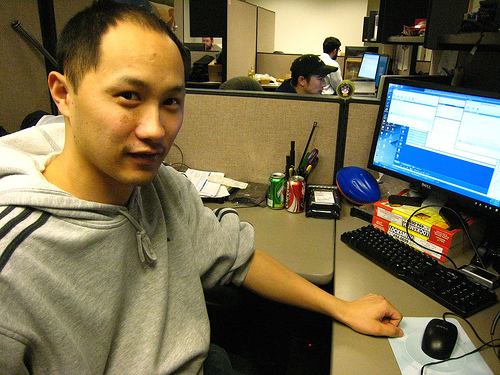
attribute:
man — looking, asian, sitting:
[0, 1, 405, 371]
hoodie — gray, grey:
[2, 120, 260, 373]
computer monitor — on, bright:
[364, 70, 499, 219]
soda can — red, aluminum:
[283, 169, 309, 216]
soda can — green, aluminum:
[264, 168, 288, 215]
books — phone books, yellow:
[369, 183, 492, 272]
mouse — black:
[418, 313, 462, 365]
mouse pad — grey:
[384, 302, 499, 373]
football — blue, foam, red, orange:
[332, 157, 385, 212]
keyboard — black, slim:
[337, 215, 499, 329]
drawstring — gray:
[119, 187, 168, 281]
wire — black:
[441, 306, 500, 352]